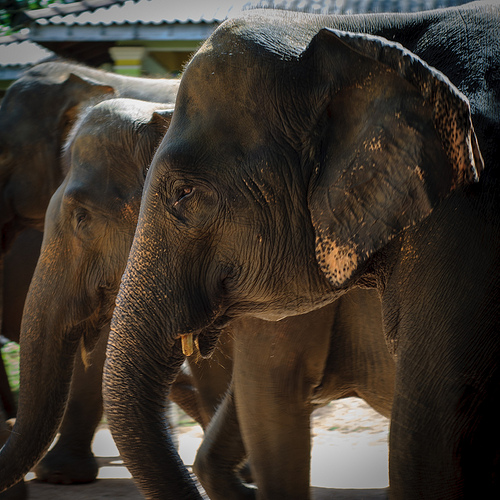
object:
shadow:
[0, 453, 391, 498]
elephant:
[0, 57, 184, 487]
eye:
[74, 210, 91, 231]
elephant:
[99, 0, 500, 500]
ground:
[0, 390, 393, 500]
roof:
[20, 0, 477, 43]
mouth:
[165, 294, 273, 362]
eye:
[173, 181, 199, 205]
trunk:
[99, 251, 208, 500]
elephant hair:
[57, 99, 95, 179]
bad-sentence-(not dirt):
[100, 319, 140, 427]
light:
[236, 5, 303, 42]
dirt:
[310, 396, 389, 496]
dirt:
[440, 86, 484, 183]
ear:
[295, 25, 487, 290]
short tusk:
[179, 326, 195, 359]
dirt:
[298, 44, 486, 292]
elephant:
[0, 95, 397, 496]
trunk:
[0, 230, 79, 496]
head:
[102, 6, 490, 500]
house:
[0, 0, 473, 82]